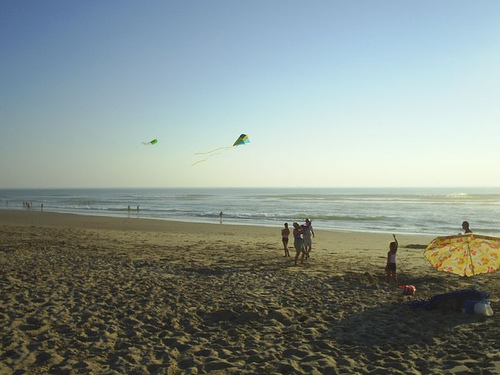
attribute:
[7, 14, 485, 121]
sky — clear, blue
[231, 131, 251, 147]
kite — big, flying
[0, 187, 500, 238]
water — calm